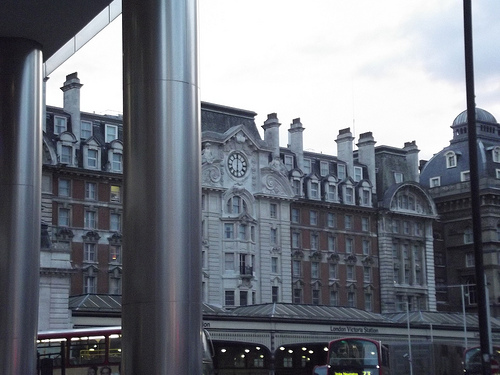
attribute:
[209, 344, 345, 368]
lights — attached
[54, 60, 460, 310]
building — victorian, brick, white, gray, red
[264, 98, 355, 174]
chimney — stack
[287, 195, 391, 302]
windows — shaped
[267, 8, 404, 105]
clouds — white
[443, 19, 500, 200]
pole — metal, black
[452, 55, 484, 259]
light — tall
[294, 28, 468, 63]
sky — blue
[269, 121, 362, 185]
roof — metal